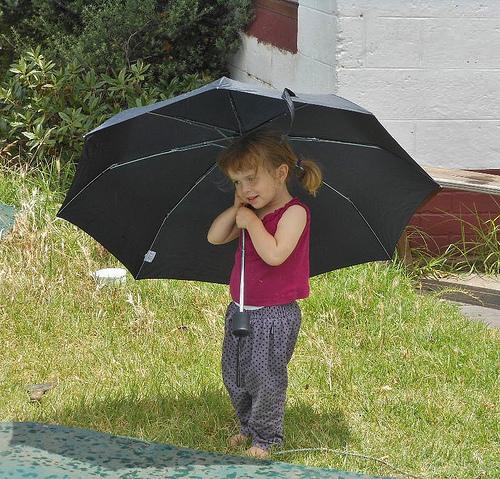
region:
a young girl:
[206, 134, 328, 461]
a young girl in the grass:
[203, 131, 328, 459]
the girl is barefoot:
[201, 133, 316, 463]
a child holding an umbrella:
[51, 70, 443, 468]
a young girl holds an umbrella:
[65, 75, 443, 456]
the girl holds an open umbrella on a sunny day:
[14, 75, 440, 462]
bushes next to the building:
[6, 1, 253, 165]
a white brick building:
[237, 1, 499, 182]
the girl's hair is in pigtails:
[211, 123, 326, 213]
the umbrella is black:
[58, 79, 447, 296]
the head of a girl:
[223, 99, 344, 222]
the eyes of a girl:
[230, 169, 267, 214]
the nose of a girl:
[232, 180, 264, 214]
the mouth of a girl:
[234, 176, 291, 214]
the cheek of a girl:
[252, 172, 278, 207]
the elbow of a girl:
[249, 223, 319, 278]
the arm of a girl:
[194, 165, 261, 279]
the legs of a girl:
[220, 331, 337, 428]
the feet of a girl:
[206, 400, 311, 474]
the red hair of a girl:
[191, 111, 338, 244]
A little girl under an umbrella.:
[129, 79, 359, 428]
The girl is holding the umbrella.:
[158, 64, 317, 403]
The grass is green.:
[30, 310, 425, 433]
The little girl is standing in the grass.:
[195, 121, 342, 409]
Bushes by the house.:
[53, 5, 255, 100]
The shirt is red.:
[218, 227, 329, 310]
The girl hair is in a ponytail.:
[262, 136, 329, 183]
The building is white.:
[322, 15, 478, 145]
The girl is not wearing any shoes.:
[219, 423, 301, 471]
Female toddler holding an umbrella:
[55, 71, 445, 464]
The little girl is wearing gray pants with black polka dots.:
[218, 302, 310, 459]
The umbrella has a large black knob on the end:
[229, 310, 254, 336]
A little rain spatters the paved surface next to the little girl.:
[1, 418, 358, 477]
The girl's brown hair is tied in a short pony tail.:
[220, 129, 323, 196]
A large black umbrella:
[60, 73, 439, 333]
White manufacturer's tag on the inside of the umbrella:
[141, 246, 157, 264]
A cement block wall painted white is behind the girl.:
[235, 1, 499, 173]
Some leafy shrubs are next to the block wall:
[2, 1, 251, 163]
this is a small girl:
[205, 130, 358, 444]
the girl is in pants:
[211, 293, 316, 429]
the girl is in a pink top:
[211, 186, 318, 292]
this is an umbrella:
[51, 80, 444, 288]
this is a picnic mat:
[4, 407, 407, 477]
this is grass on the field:
[370, 386, 453, 454]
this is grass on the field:
[312, 317, 443, 387]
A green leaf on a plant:
[108, 12, 113, 14]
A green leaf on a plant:
[129, 8, 138, 11]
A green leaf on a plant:
[44, 23, 52, 27]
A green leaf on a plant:
[60, 42, 66, 49]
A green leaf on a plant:
[79, 45, 87, 61]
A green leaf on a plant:
[29, 68, 42, 73]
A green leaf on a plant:
[100, 72, 115, 84]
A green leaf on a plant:
[117, 65, 126, 85]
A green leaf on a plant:
[137, 61, 142, 72]